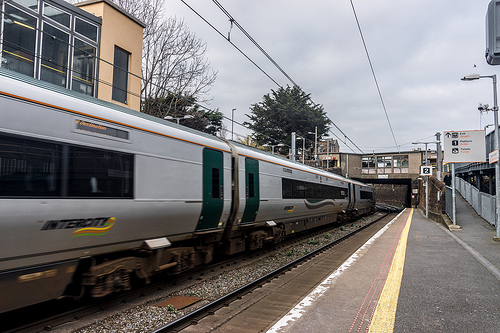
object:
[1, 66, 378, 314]
train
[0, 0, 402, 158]
wires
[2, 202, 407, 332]
rails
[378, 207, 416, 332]
line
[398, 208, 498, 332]
platform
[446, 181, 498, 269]
ramp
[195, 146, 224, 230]
door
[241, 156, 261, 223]
door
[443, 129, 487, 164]
sign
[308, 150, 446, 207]
bridge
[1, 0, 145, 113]
building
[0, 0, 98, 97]
windows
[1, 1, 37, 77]
window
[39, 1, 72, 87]
window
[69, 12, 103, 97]
window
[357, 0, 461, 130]
sky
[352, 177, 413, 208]
tunnel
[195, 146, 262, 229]
doors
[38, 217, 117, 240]
word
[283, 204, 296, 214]
word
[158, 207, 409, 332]
track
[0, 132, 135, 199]
window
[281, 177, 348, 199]
window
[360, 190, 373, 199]
window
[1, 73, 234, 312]
car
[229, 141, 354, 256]
car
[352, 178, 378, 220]
car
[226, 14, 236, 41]
wire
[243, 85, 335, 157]
tree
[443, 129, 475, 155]
directions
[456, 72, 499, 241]
pole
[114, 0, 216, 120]
tree